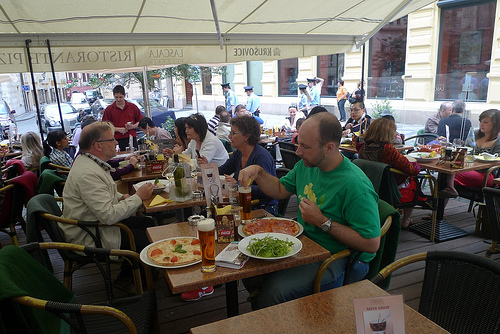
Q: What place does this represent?
A: It represents the restaurant.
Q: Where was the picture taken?
A: It was taken at the restaurant.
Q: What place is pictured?
A: It is a restaurant.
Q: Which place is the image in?
A: It is at the restaurant.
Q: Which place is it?
A: It is a restaurant.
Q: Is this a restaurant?
A: Yes, it is a restaurant.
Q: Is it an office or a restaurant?
A: It is a restaurant.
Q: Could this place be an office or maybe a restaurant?
A: It is a restaurant.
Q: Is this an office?
A: No, it is a restaurant.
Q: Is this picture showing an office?
A: No, the picture is showing a restaurant.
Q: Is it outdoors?
A: Yes, it is outdoors.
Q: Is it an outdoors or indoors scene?
A: It is outdoors.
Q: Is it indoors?
A: No, it is outdoors.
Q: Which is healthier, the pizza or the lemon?
A: The lemon is healthier than the pizza.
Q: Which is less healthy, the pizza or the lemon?
A: The pizza is less healthy than the lemon.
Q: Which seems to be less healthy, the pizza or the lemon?
A: The pizza is less healthy than the lemon.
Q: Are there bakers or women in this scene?
A: Yes, there is a woman.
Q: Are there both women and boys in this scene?
A: No, there is a woman but no boys.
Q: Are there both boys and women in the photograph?
A: No, there is a woman but no boys.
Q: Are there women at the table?
A: Yes, there is a woman at the table.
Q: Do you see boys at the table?
A: No, there is a woman at the table.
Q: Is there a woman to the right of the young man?
A: Yes, there is a woman to the right of the man.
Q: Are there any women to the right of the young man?
A: Yes, there is a woman to the right of the man.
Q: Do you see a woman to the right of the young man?
A: Yes, there is a woman to the right of the man.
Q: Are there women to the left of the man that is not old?
A: No, the woman is to the right of the man.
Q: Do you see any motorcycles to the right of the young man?
A: No, there is a woman to the right of the man.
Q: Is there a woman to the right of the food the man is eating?
A: Yes, there is a woman to the right of the food.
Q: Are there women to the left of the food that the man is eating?
A: No, the woman is to the right of the food.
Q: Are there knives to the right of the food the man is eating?
A: No, there is a woman to the right of the food.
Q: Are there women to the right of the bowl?
A: Yes, there is a woman to the right of the bowl.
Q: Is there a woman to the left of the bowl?
A: No, the woman is to the right of the bowl.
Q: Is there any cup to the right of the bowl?
A: No, there is a woman to the right of the bowl.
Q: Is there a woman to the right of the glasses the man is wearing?
A: Yes, there is a woman to the right of the glasses.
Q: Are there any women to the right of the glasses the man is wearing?
A: Yes, there is a woman to the right of the glasses.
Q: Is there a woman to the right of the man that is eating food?
A: Yes, there is a woman to the right of the man.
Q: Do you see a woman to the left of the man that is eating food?
A: No, the woman is to the right of the man.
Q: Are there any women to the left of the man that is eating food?
A: No, the woman is to the right of the man.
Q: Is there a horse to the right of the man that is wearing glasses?
A: No, there is a woman to the right of the man.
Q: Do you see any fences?
A: No, there are no fences.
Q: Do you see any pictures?
A: No, there are no pictures.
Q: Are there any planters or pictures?
A: No, there are no pictures or planters.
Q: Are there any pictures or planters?
A: No, there are no pictures or planters.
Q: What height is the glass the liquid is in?
A: The glass is tall.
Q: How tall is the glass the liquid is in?
A: The glass is tall.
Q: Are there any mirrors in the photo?
A: No, there are no mirrors.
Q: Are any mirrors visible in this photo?
A: No, there are no mirrors.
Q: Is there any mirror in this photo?
A: No, there are no mirrors.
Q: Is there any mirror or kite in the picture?
A: No, there are no mirrors or kites.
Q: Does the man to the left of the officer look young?
A: Yes, the man is young.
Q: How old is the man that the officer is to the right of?
A: The man is young.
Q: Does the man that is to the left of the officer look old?
A: No, the man is young.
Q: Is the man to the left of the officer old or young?
A: The man is young.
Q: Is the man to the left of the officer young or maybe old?
A: The man is young.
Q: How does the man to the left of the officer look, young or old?
A: The man is young.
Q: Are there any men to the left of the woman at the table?
A: Yes, there is a man to the left of the woman.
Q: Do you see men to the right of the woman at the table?
A: No, the man is to the left of the woman.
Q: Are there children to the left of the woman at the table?
A: No, there is a man to the left of the woman.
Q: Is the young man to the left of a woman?
A: Yes, the man is to the left of a woman.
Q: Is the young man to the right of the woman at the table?
A: No, the man is to the left of the woman.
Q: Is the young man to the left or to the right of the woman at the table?
A: The man is to the left of the woman.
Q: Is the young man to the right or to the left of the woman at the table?
A: The man is to the left of the woman.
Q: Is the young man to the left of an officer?
A: Yes, the man is to the left of an officer.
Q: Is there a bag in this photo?
A: No, there are no bags.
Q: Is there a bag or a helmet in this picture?
A: No, there are no bags or helmets.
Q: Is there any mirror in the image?
A: No, there are no mirrors.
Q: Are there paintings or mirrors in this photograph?
A: No, there are no mirrors or paintings.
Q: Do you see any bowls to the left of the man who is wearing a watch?
A: Yes, there is a bowl to the left of the man.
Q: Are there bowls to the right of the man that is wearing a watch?
A: No, the bowl is to the left of the man.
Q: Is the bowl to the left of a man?
A: Yes, the bowl is to the left of a man.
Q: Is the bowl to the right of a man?
A: No, the bowl is to the left of a man.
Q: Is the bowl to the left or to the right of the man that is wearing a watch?
A: The bowl is to the left of the man.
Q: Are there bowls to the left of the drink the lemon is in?
A: Yes, there is a bowl to the left of the drink.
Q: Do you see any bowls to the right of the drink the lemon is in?
A: No, the bowl is to the left of the drink.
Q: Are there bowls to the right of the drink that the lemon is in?
A: No, the bowl is to the left of the drink.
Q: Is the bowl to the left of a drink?
A: Yes, the bowl is to the left of a drink.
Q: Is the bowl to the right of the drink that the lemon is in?
A: No, the bowl is to the left of the drink.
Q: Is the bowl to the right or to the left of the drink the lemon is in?
A: The bowl is to the left of the drink.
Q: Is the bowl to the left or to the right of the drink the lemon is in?
A: The bowl is to the left of the drink.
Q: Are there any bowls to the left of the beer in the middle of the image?
A: Yes, there is a bowl to the left of the beer.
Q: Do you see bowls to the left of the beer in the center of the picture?
A: Yes, there is a bowl to the left of the beer.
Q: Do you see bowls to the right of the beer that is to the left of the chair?
A: No, the bowl is to the left of the beer.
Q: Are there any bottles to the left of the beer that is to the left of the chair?
A: No, there is a bowl to the left of the beer.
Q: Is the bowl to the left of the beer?
A: Yes, the bowl is to the left of the beer.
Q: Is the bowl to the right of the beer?
A: No, the bowl is to the left of the beer.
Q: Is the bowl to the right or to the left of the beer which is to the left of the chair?
A: The bowl is to the left of the beer.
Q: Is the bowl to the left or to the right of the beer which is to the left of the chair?
A: The bowl is to the left of the beer.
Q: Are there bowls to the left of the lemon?
A: Yes, there is a bowl to the left of the lemon.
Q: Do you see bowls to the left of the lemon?
A: Yes, there is a bowl to the left of the lemon.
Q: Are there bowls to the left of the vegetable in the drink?
A: Yes, there is a bowl to the left of the lemon.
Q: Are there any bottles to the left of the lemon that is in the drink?
A: No, there is a bowl to the left of the lemon.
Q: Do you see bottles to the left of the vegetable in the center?
A: No, there is a bowl to the left of the lemon.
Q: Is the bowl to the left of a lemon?
A: Yes, the bowl is to the left of a lemon.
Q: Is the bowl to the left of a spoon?
A: No, the bowl is to the left of a lemon.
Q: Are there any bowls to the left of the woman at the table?
A: Yes, there is a bowl to the left of the woman.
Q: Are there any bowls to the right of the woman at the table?
A: No, the bowl is to the left of the woman.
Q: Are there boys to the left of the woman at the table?
A: No, there is a bowl to the left of the woman.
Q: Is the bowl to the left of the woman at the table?
A: Yes, the bowl is to the left of the woman.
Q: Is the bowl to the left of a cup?
A: No, the bowl is to the left of the woman.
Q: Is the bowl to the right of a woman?
A: No, the bowl is to the left of a woman.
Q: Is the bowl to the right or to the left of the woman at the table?
A: The bowl is to the left of the woman.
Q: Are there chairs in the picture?
A: Yes, there is a chair.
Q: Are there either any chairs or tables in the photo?
A: Yes, there is a chair.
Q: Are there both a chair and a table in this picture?
A: Yes, there are both a chair and a table.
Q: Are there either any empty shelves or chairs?
A: Yes, there is an empty chair.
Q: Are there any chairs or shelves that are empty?
A: Yes, the chair is empty.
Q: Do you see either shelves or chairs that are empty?
A: Yes, the chair is empty.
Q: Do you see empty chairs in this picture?
A: Yes, there is an empty chair.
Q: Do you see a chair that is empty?
A: Yes, there is an empty chair.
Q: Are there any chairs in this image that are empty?
A: Yes, there is a chair that is empty.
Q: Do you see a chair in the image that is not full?
A: Yes, there is a empty chair.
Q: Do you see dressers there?
A: No, there are no dressers.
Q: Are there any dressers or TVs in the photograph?
A: No, there are no dressers or tvs.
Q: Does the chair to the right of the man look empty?
A: Yes, the chair is empty.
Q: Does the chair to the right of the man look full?
A: No, the chair is empty.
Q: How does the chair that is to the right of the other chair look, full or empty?
A: The chair is empty.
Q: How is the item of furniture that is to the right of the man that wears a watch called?
A: The piece of furniture is a chair.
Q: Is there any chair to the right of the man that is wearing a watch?
A: Yes, there is a chair to the right of the man.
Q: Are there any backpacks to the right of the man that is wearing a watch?
A: No, there is a chair to the right of the man.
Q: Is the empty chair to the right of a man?
A: Yes, the chair is to the right of a man.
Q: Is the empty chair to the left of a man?
A: No, the chair is to the right of a man.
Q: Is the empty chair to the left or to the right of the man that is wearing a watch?
A: The chair is to the right of the man.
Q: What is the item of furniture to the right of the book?
A: The piece of furniture is a chair.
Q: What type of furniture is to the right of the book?
A: The piece of furniture is a chair.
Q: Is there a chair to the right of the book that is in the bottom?
A: Yes, there is a chair to the right of the book.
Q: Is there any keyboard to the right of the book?
A: No, there is a chair to the right of the book.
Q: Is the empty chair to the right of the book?
A: Yes, the chair is to the right of the book.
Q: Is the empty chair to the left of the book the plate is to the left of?
A: No, the chair is to the right of the book.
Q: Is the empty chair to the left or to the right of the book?
A: The chair is to the right of the book.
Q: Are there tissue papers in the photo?
A: No, there are no tissue papers.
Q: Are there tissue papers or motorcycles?
A: No, there are no tissue papers or motorcycles.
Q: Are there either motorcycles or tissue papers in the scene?
A: No, there are no tissue papers or motorcycles.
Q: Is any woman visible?
A: Yes, there is a woman.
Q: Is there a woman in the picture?
A: Yes, there is a woman.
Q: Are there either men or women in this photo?
A: Yes, there is a woman.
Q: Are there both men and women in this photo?
A: Yes, there are both a woman and a man.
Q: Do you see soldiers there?
A: No, there are no soldiers.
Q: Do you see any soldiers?
A: No, there are no soldiers.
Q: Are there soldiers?
A: No, there are no soldiers.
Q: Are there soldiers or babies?
A: No, there are no soldiers or babies.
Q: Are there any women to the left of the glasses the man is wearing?
A: Yes, there is a woman to the left of the glasses.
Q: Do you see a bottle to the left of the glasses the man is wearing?
A: No, there is a woman to the left of the glasses.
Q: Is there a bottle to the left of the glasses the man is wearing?
A: No, there is a woman to the left of the glasses.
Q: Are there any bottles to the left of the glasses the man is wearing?
A: No, there is a woman to the left of the glasses.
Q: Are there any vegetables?
A: Yes, there are vegetables.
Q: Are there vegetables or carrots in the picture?
A: Yes, there are vegetables.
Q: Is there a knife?
A: No, there are no knives.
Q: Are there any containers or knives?
A: No, there are no knives or containers.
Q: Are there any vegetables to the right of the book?
A: Yes, there are vegetables to the right of the book.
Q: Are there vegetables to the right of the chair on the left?
A: Yes, there are vegetables to the right of the chair.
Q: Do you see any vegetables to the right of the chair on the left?
A: Yes, there are vegetables to the right of the chair.